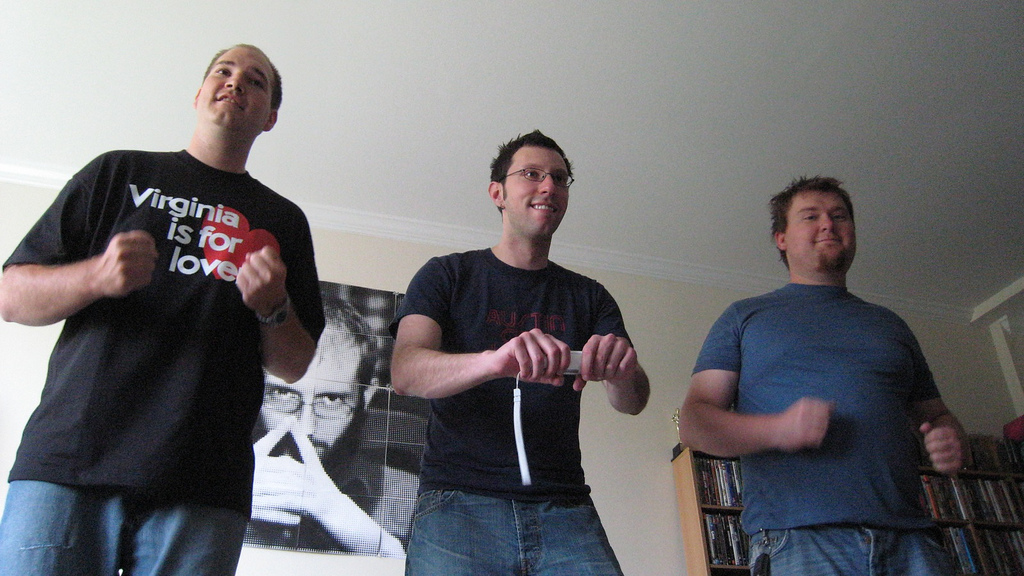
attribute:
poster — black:
[251, 278, 442, 560]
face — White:
[261, 290, 391, 487]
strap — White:
[506, 373, 541, 481]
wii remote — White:
[520, 347, 598, 377]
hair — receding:
[197, 41, 289, 112]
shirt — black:
[7, 144, 333, 533]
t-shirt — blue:
[697, 256, 948, 536]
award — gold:
[661, 400, 704, 458]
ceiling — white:
[5, 13, 1015, 342]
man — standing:
[680, 136, 979, 571]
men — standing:
[5, 40, 974, 572]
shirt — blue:
[691, 284, 961, 550]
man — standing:
[387, 127, 679, 567]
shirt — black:
[396, 242, 639, 510]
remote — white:
[491, 335, 612, 491]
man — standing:
[11, 27, 346, 572]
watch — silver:
[236, 292, 303, 334]